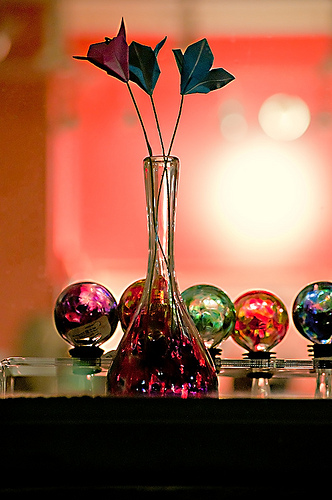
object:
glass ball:
[118, 273, 167, 334]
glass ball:
[231, 288, 289, 351]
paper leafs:
[128, 35, 167, 96]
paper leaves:
[171, 37, 237, 96]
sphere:
[292, 281, 332, 344]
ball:
[52, 281, 119, 348]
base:
[105, 329, 220, 398]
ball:
[181, 283, 236, 349]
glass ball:
[292, 281, 332, 346]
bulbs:
[53, 280, 119, 361]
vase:
[104, 155, 219, 398]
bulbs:
[292, 280, 332, 345]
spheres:
[229, 289, 290, 353]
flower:
[172, 36, 237, 95]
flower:
[71, 16, 130, 83]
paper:
[171, 37, 236, 95]